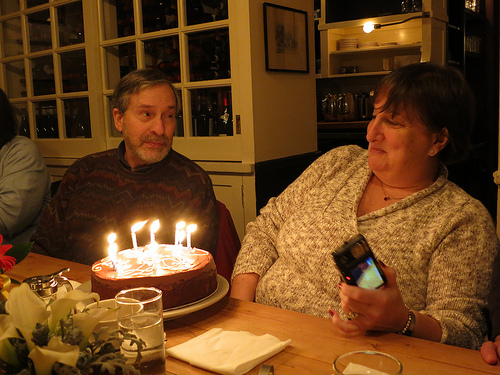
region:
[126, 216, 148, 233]
flame on top of candle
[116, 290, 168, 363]
tall glass with water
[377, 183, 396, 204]
necklace around woman's neck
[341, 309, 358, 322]
shiny ring on finger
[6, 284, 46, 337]
white flower in centerpiece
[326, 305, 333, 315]
dark red painted finger nail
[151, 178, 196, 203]
dark stripes on shirt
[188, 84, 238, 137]
glass panel in cabinet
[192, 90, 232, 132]
glass wine bottles in cabinet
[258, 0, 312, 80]
picture hanging on wall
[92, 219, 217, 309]
Chocolate birthday cake with candles.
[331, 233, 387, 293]
Black digital camera in woman's hand.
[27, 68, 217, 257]
Man in brown sweater with gray hair.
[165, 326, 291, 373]
White folded napkin on a table.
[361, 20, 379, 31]
Light bulb on in the background.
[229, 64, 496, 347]
Woman in light color sweater holding a camera.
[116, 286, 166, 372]
Glass on water on the table.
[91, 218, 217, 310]
Chocolate cake on a table.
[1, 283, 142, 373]
White flowers on a table.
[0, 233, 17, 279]
Red flower on a table.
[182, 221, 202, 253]
burning candle on a chocolate cake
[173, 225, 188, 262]
burning candle on a chocolate cake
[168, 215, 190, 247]
burning candle on a chocolate cake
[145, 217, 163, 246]
burning candle on a chocolate cake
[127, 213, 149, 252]
burning candle on a chocolate cake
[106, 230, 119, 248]
burning candle on a chocolate cake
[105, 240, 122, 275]
burning candle on a chocolate cake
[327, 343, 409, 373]
rim of a glass on the table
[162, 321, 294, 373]
white napkin sitting on the table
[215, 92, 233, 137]
wine bottle in the cabinet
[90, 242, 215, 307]
a chocolate cake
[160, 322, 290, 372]
a white napkin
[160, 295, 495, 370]
part of a wooden table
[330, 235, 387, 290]
a black camera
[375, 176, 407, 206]
part of a woman's necklace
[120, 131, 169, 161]
a man's gray beard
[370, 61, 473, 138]
a woman's short cut hair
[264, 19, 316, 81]
part of a picture frame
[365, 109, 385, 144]
the nose of a woman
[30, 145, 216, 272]
part of a man's sweater